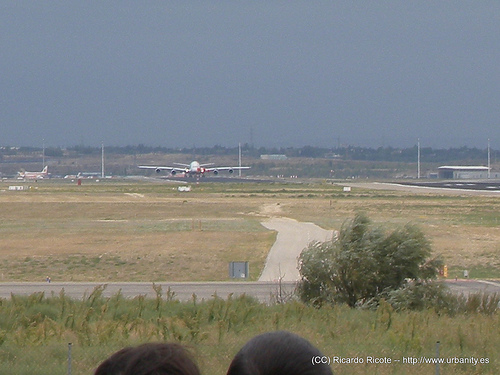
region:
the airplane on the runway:
[118, 150, 283, 194]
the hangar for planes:
[415, 158, 497, 181]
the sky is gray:
[28, 10, 440, 120]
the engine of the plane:
[150, 166, 162, 176]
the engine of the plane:
[168, 170, 179, 178]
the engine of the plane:
[215, 165, 219, 172]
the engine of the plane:
[225, 168, 236, 173]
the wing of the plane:
[137, 162, 186, 173]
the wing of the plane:
[206, 166, 255, 171]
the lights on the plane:
[182, 166, 212, 177]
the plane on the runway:
[140, 156, 250, 187]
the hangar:
[415, 155, 491, 180]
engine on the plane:
[150, 165, 165, 175]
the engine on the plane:
[170, 165, 175, 175]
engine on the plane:
[210, 166, 216, 172]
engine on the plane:
[222, 162, 232, 172]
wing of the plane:
[136, 162, 189, 172]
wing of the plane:
[196, 160, 251, 172]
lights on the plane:
[185, 166, 203, 173]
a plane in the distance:
[125, 142, 295, 199]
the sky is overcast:
[71, 51, 242, 111]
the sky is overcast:
[200, 50, 307, 92]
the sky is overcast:
[85, 66, 297, 125]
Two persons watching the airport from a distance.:
[83, 326, 338, 371]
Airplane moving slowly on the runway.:
[133, 156, 254, 178]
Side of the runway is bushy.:
[0, 293, 495, 329]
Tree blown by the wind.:
[298, 211, 444, 304]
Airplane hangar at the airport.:
[435, 161, 493, 186]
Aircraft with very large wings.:
[132, 161, 253, 173]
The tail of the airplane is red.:
[185, 161, 222, 177]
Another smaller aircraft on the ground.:
[15, 161, 53, 182]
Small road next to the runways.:
[261, 215, 336, 281]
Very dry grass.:
[11, 192, 231, 272]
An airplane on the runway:
[141, 160, 249, 180]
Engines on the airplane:
[153, 167, 236, 175]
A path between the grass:
[258, 196, 333, 283]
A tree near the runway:
[297, 218, 432, 308]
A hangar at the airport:
[436, 164, 491, 181]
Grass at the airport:
[4, 181, 499, 277]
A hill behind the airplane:
[6, 148, 498, 174]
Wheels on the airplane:
[181, 172, 206, 178]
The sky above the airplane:
[1, 1, 498, 149]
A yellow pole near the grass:
[443, 263, 450, 276]